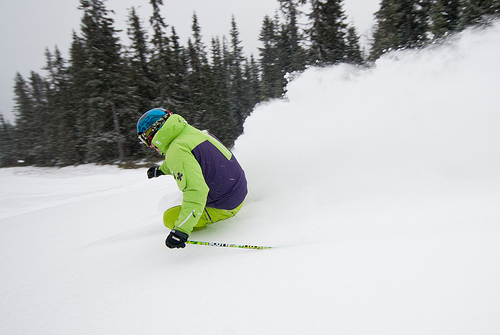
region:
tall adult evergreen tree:
[79, 5, 145, 167]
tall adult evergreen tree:
[66, 26, 86, 104]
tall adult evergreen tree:
[42, 46, 57, 86]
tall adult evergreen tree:
[26, 69, 55, 125]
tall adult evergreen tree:
[9, 70, 46, 161]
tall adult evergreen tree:
[276, 1, 306, 69]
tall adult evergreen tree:
[312, 3, 356, 60]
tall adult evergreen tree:
[221, 18, 251, 113]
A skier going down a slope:
[132, 101, 307, 261]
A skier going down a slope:
[130, 100, 295, 260]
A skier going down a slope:
[127, 96, 310, 262]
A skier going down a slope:
[131, 100, 302, 256]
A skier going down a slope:
[131, 101, 281, 256]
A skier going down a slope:
[132, 105, 292, 255]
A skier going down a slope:
[132, 105, 287, 258]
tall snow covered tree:
[371, 5, 394, 57]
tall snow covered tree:
[282, 6, 304, 68]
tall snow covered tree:
[343, 22, 363, 60]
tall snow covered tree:
[258, 15, 286, 92]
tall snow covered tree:
[244, 53, 261, 100]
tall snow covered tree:
[241, 60, 253, 104]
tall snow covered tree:
[225, 13, 254, 113]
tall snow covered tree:
[208, 37, 236, 98]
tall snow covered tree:
[185, 41, 232, 143]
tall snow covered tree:
[12, 71, 45, 165]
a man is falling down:
[102, 64, 265, 329]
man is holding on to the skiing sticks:
[149, 92, 290, 227]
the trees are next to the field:
[46, 67, 272, 127]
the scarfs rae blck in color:
[155, 219, 222, 314]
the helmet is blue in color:
[126, 95, 186, 153]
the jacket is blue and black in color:
[158, 110, 248, 223]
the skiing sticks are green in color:
[179, 224, 292, 294]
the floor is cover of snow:
[280, 120, 487, 307]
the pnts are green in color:
[167, 200, 245, 235]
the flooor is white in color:
[44, 187, 157, 332]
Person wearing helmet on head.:
[130, 112, 170, 132]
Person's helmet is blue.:
[136, 103, 173, 137]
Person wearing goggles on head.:
[128, 133, 153, 152]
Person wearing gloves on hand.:
[158, 230, 198, 255]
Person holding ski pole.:
[138, 215, 223, 267]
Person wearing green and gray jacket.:
[169, 129, 270, 237]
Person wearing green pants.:
[172, 213, 211, 227]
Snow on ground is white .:
[348, 180, 399, 270]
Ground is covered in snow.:
[41, 192, 163, 312]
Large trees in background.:
[58, 50, 216, 113]